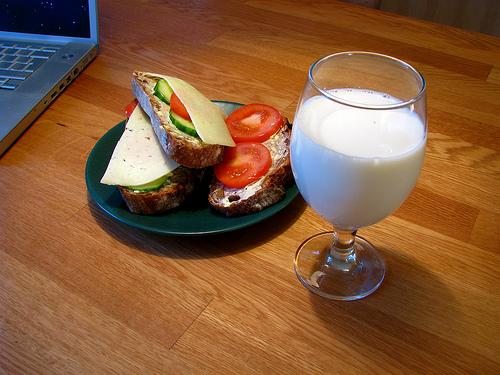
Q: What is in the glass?
A: Milk.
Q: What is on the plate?
A: Sandwiches.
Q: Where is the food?
A: On a plate.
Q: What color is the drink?
A: White.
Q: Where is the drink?
A: On a table.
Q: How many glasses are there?
A: 1.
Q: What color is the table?
A: Brown.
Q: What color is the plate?
A: Black.